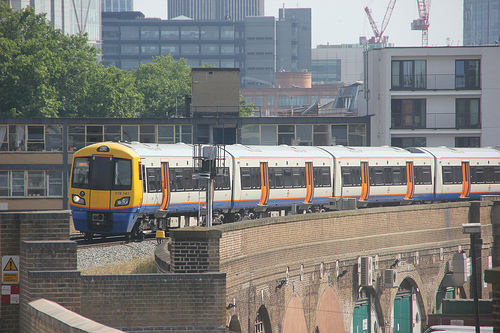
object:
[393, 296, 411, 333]
door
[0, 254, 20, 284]
sign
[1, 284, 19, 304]
sign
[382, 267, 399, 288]
air conditioning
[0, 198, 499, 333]
wall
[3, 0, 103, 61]
building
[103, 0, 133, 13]
building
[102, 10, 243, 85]
building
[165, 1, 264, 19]
building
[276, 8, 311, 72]
building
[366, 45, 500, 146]
building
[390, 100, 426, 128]
window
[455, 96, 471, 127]
window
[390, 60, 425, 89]
window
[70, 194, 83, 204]
light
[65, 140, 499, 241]
train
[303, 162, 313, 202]
door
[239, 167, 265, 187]
passenger window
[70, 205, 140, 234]
paint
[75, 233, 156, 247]
train track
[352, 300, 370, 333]
doors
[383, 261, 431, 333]
arches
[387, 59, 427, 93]
balcony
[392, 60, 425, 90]
sliding door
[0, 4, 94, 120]
treetops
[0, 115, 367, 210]
building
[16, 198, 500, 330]
railway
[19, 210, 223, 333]
brick wall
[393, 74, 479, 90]
railing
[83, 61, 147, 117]
trees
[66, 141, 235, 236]
engine car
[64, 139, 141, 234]
front